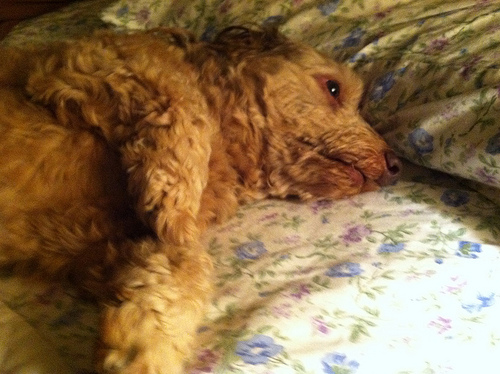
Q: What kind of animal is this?
A: Dog.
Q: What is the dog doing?
A: Lying down.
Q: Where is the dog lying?
A: Bed.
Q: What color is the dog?
A: Tan.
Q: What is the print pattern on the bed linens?
A: Floral.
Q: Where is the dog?
A: On a bed.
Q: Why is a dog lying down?
A: To sleep.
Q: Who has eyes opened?
A: The dog.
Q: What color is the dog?
A: Brown.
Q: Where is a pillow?
A: On bed.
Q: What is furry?
A: A dog.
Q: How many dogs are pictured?
A: One.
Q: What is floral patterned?
A: Bed sheets.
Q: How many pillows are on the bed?
A: One.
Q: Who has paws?
A: Dog.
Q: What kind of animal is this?
A: Dog.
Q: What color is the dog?
A: Tan.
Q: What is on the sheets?
A: Flowers.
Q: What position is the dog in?
A: Laying down.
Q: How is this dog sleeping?
A: Dog is not sleeping.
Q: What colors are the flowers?
A: Purple, blue, white.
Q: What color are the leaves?
A: Green.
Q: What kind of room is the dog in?
A: Bedroom.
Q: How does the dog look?
A: Tired.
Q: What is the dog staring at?
A: Light.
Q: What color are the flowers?
A: Blue.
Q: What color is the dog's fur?
A: Brown.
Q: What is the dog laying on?
A: A sheet.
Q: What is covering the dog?
A: Hair.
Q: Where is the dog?
A: In bed.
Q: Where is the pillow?
A: By the head.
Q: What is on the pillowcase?
A: Flowers.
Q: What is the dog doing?
A: Laying down.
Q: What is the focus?
A: Dog in bed.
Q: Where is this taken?
A: Bedroom.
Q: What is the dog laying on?
A: Bed.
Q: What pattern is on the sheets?
A: Flowers.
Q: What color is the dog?
A: Brown.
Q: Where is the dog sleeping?
A: Bed.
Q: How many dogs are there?
A: 1.